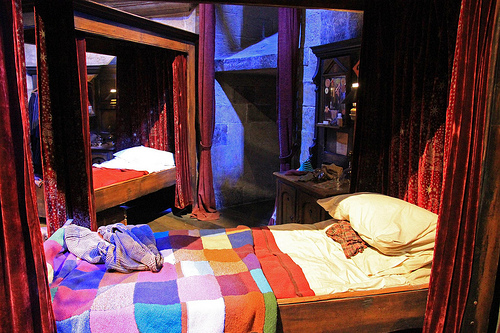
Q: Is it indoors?
A: Yes, it is indoors.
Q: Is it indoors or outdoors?
A: It is indoors.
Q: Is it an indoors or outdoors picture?
A: It is indoors.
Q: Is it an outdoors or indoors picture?
A: It is indoors.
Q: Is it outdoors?
A: No, it is indoors.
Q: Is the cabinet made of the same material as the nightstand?
A: Yes, both the cabinet and the nightstand are made of wood.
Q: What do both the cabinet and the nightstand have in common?
A: The material, both the cabinet and the nightstand are wooden.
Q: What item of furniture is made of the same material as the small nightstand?
A: The cabinet is made of the same material as the nightstand.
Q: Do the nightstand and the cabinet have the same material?
A: Yes, both the nightstand and the cabinet are made of wood.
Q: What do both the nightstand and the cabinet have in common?
A: The material, both the nightstand and the cabinet are wooden.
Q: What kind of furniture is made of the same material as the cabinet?
A: The nightstand is made of the same material as the cabinet.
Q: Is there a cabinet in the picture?
A: Yes, there is a cabinet.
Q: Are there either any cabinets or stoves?
A: Yes, there is a cabinet.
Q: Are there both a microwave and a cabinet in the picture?
A: No, there is a cabinet but no microwaves.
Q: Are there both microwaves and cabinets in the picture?
A: No, there is a cabinet but no microwaves.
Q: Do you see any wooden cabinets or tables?
A: Yes, there is a wood cabinet.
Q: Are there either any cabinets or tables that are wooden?
A: Yes, the cabinet is wooden.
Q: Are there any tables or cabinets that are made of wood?
A: Yes, the cabinet is made of wood.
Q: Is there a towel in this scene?
A: No, there are no towels.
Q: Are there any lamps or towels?
A: No, there are no towels or lamps.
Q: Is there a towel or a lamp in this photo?
A: No, there are no towels or lamps.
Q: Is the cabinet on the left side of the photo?
A: Yes, the cabinet is on the left of the image.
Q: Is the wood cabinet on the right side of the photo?
A: No, the cabinet is on the left of the image.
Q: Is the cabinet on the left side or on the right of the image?
A: The cabinet is on the left of the image.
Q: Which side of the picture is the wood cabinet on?
A: The cabinet is on the left of the image.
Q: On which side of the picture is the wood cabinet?
A: The cabinet is on the left of the image.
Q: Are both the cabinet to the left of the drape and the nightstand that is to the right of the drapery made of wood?
A: Yes, both the cabinet and the nightstand are made of wood.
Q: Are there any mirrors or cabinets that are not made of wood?
A: No, there is a cabinet but it is made of wood.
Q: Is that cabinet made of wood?
A: Yes, the cabinet is made of wood.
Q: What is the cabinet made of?
A: The cabinet is made of wood.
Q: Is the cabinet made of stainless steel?
A: No, the cabinet is made of wood.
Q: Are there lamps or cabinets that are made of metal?
A: No, there is a cabinet but it is made of wood.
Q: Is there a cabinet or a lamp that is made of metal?
A: No, there is a cabinet but it is made of wood.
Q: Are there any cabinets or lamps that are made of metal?
A: No, there is a cabinet but it is made of wood.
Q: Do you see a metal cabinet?
A: No, there is a cabinet but it is made of wood.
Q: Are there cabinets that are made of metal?
A: No, there is a cabinet but it is made of wood.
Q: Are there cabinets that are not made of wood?
A: No, there is a cabinet but it is made of wood.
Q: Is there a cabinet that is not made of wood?
A: No, there is a cabinet but it is made of wood.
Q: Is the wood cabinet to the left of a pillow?
A: Yes, the cabinet is to the left of a pillow.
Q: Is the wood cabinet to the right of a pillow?
A: No, the cabinet is to the left of a pillow.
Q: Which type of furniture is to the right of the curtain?
A: The piece of furniture is a cabinet.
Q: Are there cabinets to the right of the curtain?
A: Yes, there is a cabinet to the right of the curtain.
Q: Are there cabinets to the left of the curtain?
A: No, the cabinet is to the right of the curtain.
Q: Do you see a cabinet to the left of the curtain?
A: No, the cabinet is to the right of the curtain.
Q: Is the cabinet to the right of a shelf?
A: No, the cabinet is to the right of the curtain.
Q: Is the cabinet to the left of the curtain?
A: No, the cabinet is to the right of the curtain.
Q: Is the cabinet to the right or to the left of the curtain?
A: The cabinet is to the right of the curtain.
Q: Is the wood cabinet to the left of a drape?
A: Yes, the cabinet is to the left of a drape.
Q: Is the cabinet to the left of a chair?
A: No, the cabinet is to the left of a drape.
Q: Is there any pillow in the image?
A: Yes, there is a pillow.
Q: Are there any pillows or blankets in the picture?
A: Yes, there is a pillow.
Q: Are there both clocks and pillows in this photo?
A: No, there is a pillow but no clocks.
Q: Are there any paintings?
A: No, there are no paintings.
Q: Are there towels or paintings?
A: No, there are no paintings or towels.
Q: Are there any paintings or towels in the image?
A: No, there are no paintings or towels.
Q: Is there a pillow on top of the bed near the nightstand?
A: Yes, there is a pillow on top of the bed.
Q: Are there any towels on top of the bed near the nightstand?
A: No, there is a pillow on top of the bed.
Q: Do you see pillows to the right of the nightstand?
A: Yes, there is a pillow to the right of the nightstand.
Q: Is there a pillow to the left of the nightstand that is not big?
A: No, the pillow is to the right of the nightstand.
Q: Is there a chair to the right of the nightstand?
A: No, there is a pillow to the right of the nightstand.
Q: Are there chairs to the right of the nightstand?
A: No, there is a pillow to the right of the nightstand.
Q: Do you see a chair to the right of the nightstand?
A: No, there is a pillow to the right of the nightstand.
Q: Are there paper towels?
A: No, there are no paper towels.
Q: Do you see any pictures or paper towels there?
A: No, there are no paper towels or pictures.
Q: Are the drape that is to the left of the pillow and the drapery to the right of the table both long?
A: Yes, both the drapery and the drape are long.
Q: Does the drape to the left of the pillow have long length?
A: Yes, the drapery is long.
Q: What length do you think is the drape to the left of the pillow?
A: The drape is long.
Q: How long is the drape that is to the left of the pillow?
A: The drape is long.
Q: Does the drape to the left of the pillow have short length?
A: No, the drapery is long.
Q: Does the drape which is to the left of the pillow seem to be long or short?
A: The drapery is long.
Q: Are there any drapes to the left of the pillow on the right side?
A: Yes, there is a drape to the left of the pillow.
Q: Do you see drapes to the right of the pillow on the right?
A: No, the drape is to the left of the pillow.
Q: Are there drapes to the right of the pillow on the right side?
A: No, the drape is to the left of the pillow.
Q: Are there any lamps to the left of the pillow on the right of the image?
A: No, there is a drape to the left of the pillow.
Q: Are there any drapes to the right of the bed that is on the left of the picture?
A: Yes, there is a drape to the right of the bed.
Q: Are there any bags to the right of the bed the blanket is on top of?
A: No, there is a drape to the right of the bed.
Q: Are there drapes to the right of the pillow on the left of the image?
A: Yes, there is a drape to the right of the pillow.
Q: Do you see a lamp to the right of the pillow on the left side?
A: No, there is a drape to the right of the pillow.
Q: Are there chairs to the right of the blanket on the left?
A: No, there is a drape to the right of the blanket.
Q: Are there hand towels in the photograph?
A: No, there are no hand towels.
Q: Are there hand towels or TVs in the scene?
A: No, there are no hand towels or tvs.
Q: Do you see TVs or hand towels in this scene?
A: No, there are no hand towels or tvs.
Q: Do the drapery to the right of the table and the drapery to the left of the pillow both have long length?
A: Yes, both the drapery and the drapery are long.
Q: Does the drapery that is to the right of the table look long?
A: Yes, the drape is long.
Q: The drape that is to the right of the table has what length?
A: The drapery is long.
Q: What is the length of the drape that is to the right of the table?
A: The drapery is long.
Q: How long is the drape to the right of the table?
A: The drape is long.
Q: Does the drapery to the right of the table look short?
A: No, the drape is long.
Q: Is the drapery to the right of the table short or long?
A: The drapery is long.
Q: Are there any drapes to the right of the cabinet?
A: Yes, there is a drape to the right of the cabinet.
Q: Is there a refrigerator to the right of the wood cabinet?
A: No, there is a drape to the right of the cabinet.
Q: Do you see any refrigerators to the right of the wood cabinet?
A: No, there is a drape to the right of the cabinet.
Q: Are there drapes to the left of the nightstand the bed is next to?
A: Yes, there is a drape to the left of the nightstand.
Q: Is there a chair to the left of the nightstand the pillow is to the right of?
A: No, there is a drape to the left of the nightstand.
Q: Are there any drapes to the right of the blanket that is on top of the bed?
A: Yes, there is a drape to the right of the blanket.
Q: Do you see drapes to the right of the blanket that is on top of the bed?
A: Yes, there is a drape to the right of the blanket.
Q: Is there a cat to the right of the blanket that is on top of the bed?
A: No, there is a drape to the right of the blanket.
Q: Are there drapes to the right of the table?
A: Yes, there is a drape to the right of the table.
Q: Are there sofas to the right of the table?
A: No, there is a drape to the right of the table.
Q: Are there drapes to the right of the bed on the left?
A: Yes, there is a drape to the right of the bed.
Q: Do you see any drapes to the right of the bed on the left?
A: Yes, there is a drape to the right of the bed.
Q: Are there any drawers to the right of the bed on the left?
A: No, there is a drape to the right of the bed.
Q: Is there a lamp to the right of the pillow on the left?
A: No, there is a drape to the right of the pillow.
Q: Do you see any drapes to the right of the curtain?
A: Yes, there is a drape to the right of the curtain.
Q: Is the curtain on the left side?
A: Yes, the curtain is on the left of the image.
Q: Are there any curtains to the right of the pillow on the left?
A: No, the curtain is to the left of the pillow.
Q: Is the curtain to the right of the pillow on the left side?
A: No, the curtain is to the left of the pillow.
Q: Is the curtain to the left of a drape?
A: Yes, the curtain is to the left of a drape.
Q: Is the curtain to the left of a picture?
A: No, the curtain is to the left of a drape.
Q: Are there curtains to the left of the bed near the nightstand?
A: Yes, there is a curtain to the left of the bed.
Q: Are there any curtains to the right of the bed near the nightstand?
A: No, the curtain is to the left of the bed.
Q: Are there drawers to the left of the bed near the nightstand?
A: No, there is a curtain to the left of the bed.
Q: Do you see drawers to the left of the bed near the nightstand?
A: No, there is a curtain to the left of the bed.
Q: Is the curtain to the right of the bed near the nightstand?
A: No, the curtain is to the left of the bed.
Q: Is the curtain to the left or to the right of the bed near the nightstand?
A: The curtain is to the left of the bed.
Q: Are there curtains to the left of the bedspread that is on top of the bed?
A: Yes, there is a curtain to the left of the bedspread.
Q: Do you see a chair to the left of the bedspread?
A: No, there is a curtain to the left of the bedspread.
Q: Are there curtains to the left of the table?
A: Yes, there is a curtain to the left of the table.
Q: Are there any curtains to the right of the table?
A: No, the curtain is to the left of the table.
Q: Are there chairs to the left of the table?
A: No, there is a curtain to the left of the table.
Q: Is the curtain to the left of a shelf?
A: No, the curtain is to the left of a table.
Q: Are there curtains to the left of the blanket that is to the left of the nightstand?
A: Yes, there is a curtain to the left of the blanket.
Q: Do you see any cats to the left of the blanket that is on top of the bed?
A: No, there is a curtain to the left of the blanket.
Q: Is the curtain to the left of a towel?
A: No, the curtain is to the left of a blanket.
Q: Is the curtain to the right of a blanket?
A: No, the curtain is to the left of a blanket.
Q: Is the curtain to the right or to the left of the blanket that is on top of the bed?
A: The curtain is to the left of the blanket.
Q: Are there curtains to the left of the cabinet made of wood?
A: Yes, there is a curtain to the left of the cabinet.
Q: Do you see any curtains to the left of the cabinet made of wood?
A: Yes, there is a curtain to the left of the cabinet.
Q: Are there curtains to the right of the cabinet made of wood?
A: No, the curtain is to the left of the cabinet.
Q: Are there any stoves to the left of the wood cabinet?
A: No, there is a curtain to the left of the cabinet.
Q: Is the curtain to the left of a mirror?
A: No, the curtain is to the left of a cabinet.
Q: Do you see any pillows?
A: Yes, there is a pillow.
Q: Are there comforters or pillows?
A: Yes, there is a pillow.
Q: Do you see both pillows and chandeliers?
A: No, there is a pillow but no chandeliers.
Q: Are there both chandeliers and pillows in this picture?
A: No, there is a pillow but no chandeliers.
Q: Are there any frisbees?
A: No, there are no frisbees.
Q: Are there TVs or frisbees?
A: No, there are no frisbees or tvs.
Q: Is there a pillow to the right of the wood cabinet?
A: Yes, there is a pillow to the right of the cabinet.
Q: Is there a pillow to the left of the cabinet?
A: No, the pillow is to the right of the cabinet.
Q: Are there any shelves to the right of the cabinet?
A: No, there is a pillow to the right of the cabinet.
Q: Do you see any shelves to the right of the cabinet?
A: No, there is a pillow to the right of the cabinet.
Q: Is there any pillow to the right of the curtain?
A: Yes, there is a pillow to the right of the curtain.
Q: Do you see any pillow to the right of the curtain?
A: Yes, there is a pillow to the right of the curtain.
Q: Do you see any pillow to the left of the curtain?
A: No, the pillow is to the right of the curtain.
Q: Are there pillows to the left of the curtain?
A: No, the pillow is to the right of the curtain.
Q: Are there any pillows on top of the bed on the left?
A: Yes, there is a pillow on top of the bed.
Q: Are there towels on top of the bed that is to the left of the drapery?
A: No, there is a pillow on top of the bed.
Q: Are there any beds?
A: Yes, there is a bed.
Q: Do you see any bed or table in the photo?
A: Yes, there is a bed.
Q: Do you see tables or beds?
A: Yes, there is a bed.